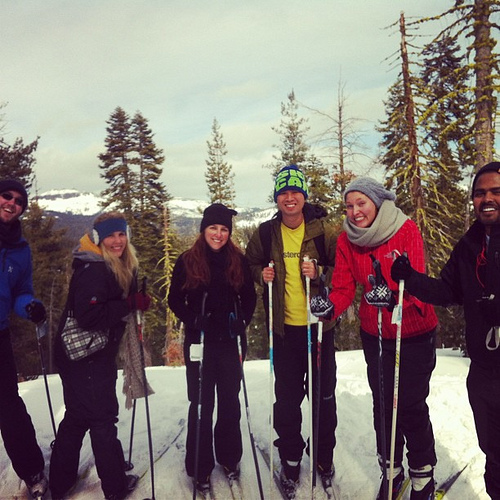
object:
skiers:
[0, 160, 500, 500]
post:
[192, 292, 210, 500]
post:
[267, 261, 275, 499]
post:
[30, 300, 57, 437]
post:
[304, 256, 315, 499]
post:
[311, 267, 331, 500]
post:
[127, 275, 148, 469]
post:
[131, 266, 154, 500]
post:
[387, 251, 408, 500]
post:
[237, 334, 266, 499]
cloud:
[163, 140, 208, 174]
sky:
[2, 3, 498, 208]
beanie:
[199, 202, 238, 235]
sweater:
[327, 218, 438, 338]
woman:
[166, 202, 257, 493]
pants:
[184, 327, 248, 480]